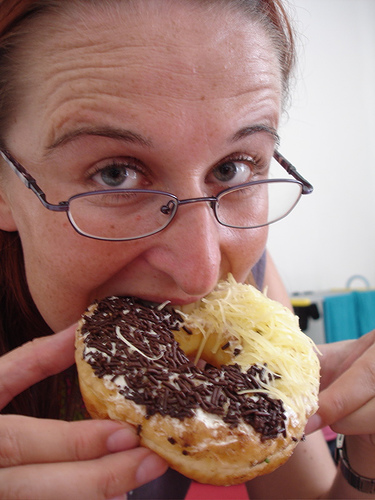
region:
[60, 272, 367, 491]
the donut has sprinkles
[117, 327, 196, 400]
the sprikles are brown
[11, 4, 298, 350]
the girl is white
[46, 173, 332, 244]
the girl wears glasses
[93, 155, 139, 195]
her eyes are blue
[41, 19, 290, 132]
her forehead is so large and in charge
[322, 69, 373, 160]
the wall is white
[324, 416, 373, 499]
the girl has a watch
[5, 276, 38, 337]
the shirt is red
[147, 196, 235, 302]
her nose is big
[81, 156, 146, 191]
Right eye of a person.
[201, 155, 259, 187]
Left eye of a person.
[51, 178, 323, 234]
A wire frame pair of glasses.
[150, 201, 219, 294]
The nose of a female.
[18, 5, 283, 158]
The forehead of a woman.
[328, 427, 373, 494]
part of a wristwatch on wrist.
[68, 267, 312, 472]
A delicious doughnut being eaten.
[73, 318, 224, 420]
Sweet brown sprinkles on a doughnut.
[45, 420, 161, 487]
Two fingers of a woman.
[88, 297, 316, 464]
A beautiful doughnut with blended flavors.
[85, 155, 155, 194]
a woman's eye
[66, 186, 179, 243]
one lens from a pair of glasses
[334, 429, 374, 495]
a wristwatch band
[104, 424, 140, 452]
a fingernail of the woman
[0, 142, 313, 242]
a pair of glasses on the woman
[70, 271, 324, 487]
a donut in the woman's hands and mouth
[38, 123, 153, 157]
an eyebrow of the woman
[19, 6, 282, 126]
the woman's forehead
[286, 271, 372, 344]
two blue and white bags in the background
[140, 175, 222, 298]
the nose of the woman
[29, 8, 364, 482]
a woman eating a doughnut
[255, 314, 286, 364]
coconut frosting on a doughnut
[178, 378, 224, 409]
chocolate sprinkles on a doughnut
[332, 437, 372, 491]
a metal watch on a wrist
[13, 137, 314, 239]
eyeglasses covering eyes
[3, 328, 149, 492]
finger grasping a doughnut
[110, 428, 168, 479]
fingernails on white fingers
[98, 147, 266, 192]
two blue eyes on a face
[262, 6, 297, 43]
brown hair growing on a head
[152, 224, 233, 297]
a nose with red freckles on it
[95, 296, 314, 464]
this is a doughnut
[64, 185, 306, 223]
this is a pair of spectacles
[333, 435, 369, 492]
this is a wrist watch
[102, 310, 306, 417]
the doughnut is big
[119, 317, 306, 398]
the doughnut has some sprinkles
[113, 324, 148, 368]
the sprinkles are brown in color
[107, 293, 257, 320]
the woman is biting the doughnut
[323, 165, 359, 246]
this is the wall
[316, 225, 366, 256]
the wall is white in color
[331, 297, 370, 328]
this is a blue cloth